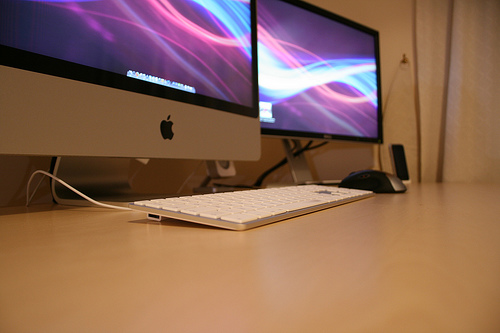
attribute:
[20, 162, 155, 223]
cord — white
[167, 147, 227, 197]
cord — white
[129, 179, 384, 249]
keyboard — white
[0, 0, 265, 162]
monitor — turned on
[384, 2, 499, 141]
wall — yellow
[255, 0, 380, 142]
monitor — black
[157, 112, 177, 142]
logo — Apple , black